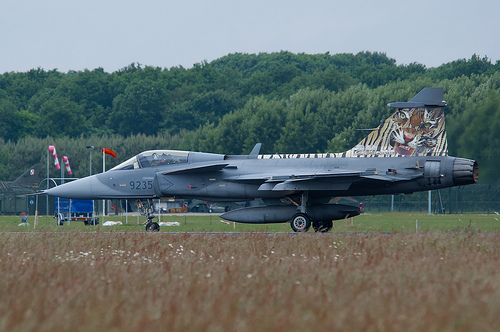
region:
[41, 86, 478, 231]
a military jet on the runway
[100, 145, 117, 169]
a red windsock on the runway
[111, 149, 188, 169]
the pilots glass cockpit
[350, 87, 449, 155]
the jets tail with a tiger image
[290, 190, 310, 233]
the jets landing gear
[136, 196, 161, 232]
the jets front landing gear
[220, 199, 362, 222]
fuel tanks under the wing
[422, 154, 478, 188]
turbine jet engine exhaust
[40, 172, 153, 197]
the jets cone nose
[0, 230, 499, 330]
a grass field along the runway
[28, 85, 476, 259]
fighter jet in the grass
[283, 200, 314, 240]
wheels of a jet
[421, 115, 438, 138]
eye of a tiger on tail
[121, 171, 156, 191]
number on a jet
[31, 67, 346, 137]
green trees behind fields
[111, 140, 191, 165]
cockpit of a jet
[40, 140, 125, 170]
flags in a field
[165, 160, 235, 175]
wing of a jet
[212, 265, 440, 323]
brown grass of a field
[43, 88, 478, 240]
Gray jet in field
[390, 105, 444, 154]
Tiger image on tail of plane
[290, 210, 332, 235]
Landing gear of plane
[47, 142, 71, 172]
Red and white wind socks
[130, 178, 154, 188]
Black numbers on the side of the plane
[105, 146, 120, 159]
Red wind sock in field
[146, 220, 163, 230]
Front landing gear on plane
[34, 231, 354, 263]
White flowers in field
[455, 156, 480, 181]
Tail end of plane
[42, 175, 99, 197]
Pointed nose cone of plane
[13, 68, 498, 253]
a fighter jet on a runway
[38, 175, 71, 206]
the nosecone of a fighter jet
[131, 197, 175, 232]
the landing gear of a fighter jet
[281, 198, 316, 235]
the landing gear of a fighter jet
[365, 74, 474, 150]
the tail-fin of a fighter jet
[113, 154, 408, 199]
the fuselage of a fighter jet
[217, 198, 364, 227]
a bomb of a fighter jet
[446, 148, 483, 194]
the tail thruster of a fighter jet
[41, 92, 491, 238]
large gray fighter jet on runway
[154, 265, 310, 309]
brown bush in the field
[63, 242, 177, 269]
white flowers in the bushes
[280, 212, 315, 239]
wheel on fighter jet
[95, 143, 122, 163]
red flag on pole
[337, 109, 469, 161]
animal print on plane's tail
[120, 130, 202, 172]
gray cockpit on front of plane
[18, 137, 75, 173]
pink and white banner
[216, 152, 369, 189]
gray wing on the plane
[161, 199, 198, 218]
orange barrels on the ground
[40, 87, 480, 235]
large metal grey jet plane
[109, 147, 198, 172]
large domed glass window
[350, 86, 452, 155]
large tall tiger painted tail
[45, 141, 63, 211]
tall red and white flag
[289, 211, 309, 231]
small round black tire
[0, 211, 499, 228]
large wide grassy area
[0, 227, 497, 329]
large wide brown grass area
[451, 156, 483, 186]
small round metal jet tail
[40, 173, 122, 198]
long pointy jet nose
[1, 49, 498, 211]
large green wide forest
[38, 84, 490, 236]
A military jet on the ground.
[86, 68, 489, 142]
The trees are green.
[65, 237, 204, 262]
white flowers on the grass.